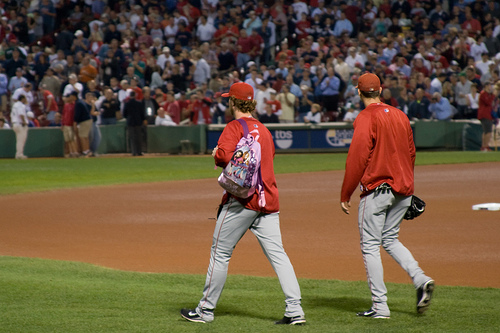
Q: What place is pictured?
A: It is a field.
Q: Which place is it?
A: It is a field.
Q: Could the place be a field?
A: Yes, it is a field.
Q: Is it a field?
A: Yes, it is a field.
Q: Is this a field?
A: Yes, it is a field.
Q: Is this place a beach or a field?
A: It is a field.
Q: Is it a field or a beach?
A: It is a field.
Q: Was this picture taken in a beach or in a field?
A: It was taken at a field.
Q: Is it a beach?
A: No, it is a field.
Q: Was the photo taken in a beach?
A: No, the picture was taken in a field.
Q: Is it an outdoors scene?
A: Yes, it is outdoors.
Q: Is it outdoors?
A: Yes, it is outdoors.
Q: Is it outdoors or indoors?
A: It is outdoors.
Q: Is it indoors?
A: No, it is outdoors.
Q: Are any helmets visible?
A: No, there are no helmets.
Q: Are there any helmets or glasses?
A: No, there are no helmets or glasses.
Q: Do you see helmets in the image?
A: No, there are no helmets.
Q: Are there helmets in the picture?
A: No, there are no helmets.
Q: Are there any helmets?
A: No, there are no helmets.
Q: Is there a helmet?
A: No, there are no helmets.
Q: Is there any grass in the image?
A: Yes, there is grass.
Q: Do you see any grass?
A: Yes, there is grass.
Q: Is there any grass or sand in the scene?
A: Yes, there is grass.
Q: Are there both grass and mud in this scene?
A: No, there is grass but no mud.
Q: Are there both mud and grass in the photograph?
A: No, there is grass but no mud.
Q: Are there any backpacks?
A: Yes, there is a backpack.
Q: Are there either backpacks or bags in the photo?
A: Yes, there is a backpack.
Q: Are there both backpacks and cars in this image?
A: No, there is a backpack but no cars.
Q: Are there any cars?
A: No, there are no cars.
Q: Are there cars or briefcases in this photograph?
A: No, there are no cars or briefcases.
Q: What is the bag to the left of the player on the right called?
A: The bag is a backpack.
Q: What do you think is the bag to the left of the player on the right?
A: The bag is a backpack.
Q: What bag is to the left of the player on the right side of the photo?
A: The bag is a backpack.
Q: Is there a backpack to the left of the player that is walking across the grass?
A: Yes, there is a backpack to the left of the player.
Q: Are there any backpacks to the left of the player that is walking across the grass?
A: Yes, there is a backpack to the left of the player.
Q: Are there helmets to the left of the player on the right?
A: No, there is a backpack to the left of the player.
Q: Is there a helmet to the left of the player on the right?
A: No, there is a backpack to the left of the player.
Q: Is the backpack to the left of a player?
A: Yes, the backpack is to the left of a player.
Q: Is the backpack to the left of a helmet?
A: No, the backpack is to the left of a player.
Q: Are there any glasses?
A: No, there are no glasses.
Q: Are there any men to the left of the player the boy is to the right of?
A: Yes, there is a man to the left of the player.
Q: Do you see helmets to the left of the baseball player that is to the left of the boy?
A: No, there is a man to the left of the player.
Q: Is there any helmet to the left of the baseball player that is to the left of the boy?
A: No, there is a man to the left of the player.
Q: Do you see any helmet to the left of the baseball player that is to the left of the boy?
A: No, there is a man to the left of the player.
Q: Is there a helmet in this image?
A: No, there are no helmets.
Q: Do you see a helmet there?
A: No, there are no helmets.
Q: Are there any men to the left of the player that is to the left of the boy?
A: Yes, there is a man to the left of the player.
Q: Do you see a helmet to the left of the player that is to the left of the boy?
A: No, there is a man to the left of the player.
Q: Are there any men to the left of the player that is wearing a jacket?
A: Yes, there is a man to the left of the player.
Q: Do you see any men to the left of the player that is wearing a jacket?
A: Yes, there is a man to the left of the player.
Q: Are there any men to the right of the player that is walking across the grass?
A: No, the man is to the left of the player.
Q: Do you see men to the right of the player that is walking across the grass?
A: No, the man is to the left of the player.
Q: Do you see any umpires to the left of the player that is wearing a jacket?
A: No, there is a man to the left of the player.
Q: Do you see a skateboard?
A: No, there are no skateboards.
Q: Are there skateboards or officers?
A: No, there are no skateboards or officers.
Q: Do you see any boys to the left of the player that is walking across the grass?
A: Yes, there is a boy to the left of the player.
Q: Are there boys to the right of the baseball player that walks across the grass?
A: No, the boy is to the left of the player.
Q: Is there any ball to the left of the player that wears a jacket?
A: No, there is a boy to the left of the player.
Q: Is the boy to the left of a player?
A: Yes, the boy is to the left of a player.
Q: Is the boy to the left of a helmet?
A: No, the boy is to the left of a player.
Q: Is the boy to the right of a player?
A: No, the boy is to the left of a player.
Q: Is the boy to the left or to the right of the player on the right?
A: The boy is to the left of the player.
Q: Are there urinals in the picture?
A: No, there are no urinals.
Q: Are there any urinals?
A: No, there are no urinals.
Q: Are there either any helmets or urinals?
A: No, there are no urinals or helmets.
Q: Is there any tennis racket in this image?
A: No, there are no rackets.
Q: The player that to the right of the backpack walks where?
A: The player walks on the field.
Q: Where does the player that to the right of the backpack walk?
A: The player walks on the field.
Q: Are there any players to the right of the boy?
A: Yes, there is a player to the right of the boy.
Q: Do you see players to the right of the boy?
A: Yes, there is a player to the right of the boy.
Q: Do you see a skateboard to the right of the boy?
A: No, there is a player to the right of the boy.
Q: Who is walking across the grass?
A: The player is walking across the grass.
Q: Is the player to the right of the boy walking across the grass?
A: Yes, the player is walking across the grass.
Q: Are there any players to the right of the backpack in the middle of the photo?
A: Yes, there is a player to the right of the backpack.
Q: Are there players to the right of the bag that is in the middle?
A: Yes, there is a player to the right of the backpack.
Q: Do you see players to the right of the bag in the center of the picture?
A: Yes, there is a player to the right of the backpack.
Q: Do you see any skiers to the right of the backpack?
A: No, there is a player to the right of the backpack.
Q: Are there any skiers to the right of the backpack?
A: No, there is a player to the right of the backpack.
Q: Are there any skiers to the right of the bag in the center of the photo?
A: No, there is a player to the right of the backpack.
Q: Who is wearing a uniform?
A: The player is wearing a uniform.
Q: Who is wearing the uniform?
A: The player is wearing a uniform.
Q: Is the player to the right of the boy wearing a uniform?
A: Yes, the player is wearing a uniform.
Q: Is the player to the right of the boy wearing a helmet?
A: No, the player is wearing a uniform.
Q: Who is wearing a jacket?
A: The player is wearing a jacket.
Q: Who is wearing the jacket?
A: The player is wearing a jacket.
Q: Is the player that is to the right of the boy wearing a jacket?
A: Yes, the player is wearing a jacket.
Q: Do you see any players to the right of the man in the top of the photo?
A: Yes, there is a player to the right of the man.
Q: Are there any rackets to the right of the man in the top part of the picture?
A: No, there is a player to the right of the man.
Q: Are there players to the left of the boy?
A: Yes, there is a player to the left of the boy.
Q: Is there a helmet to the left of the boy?
A: No, there is a player to the left of the boy.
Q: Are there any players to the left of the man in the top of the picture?
A: Yes, there is a player to the left of the man.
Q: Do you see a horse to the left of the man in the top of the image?
A: No, there is a player to the left of the man.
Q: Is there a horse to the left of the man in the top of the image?
A: No, there is a player to the left of the man.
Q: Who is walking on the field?
A: The player is walking on the field.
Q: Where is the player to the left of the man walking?
A: The player is walking on the field.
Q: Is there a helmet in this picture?
A: No, there are no helmets.